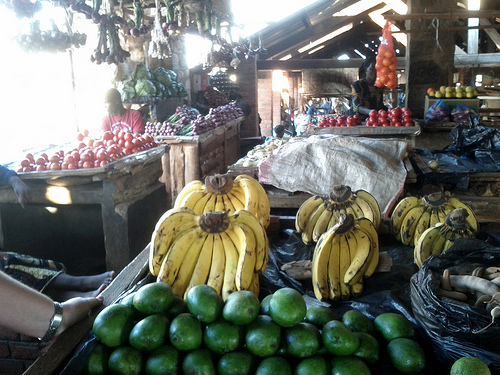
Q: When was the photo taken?
A: Daytime.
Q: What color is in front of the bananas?
A: Green.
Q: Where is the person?
A: Beside the tomatoes.